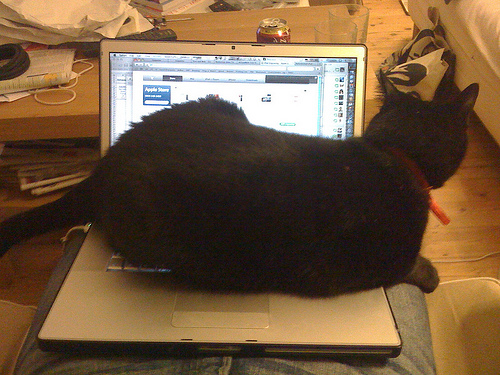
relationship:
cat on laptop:
[0, 67, 479, 294] [34, 36, 404, 361]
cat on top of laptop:
[0, 67, 479, 294] [44, 49, 419, 349]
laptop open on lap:
[34, 36, 404, 361] [27, 226, 439, 370]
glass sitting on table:
[311, 19, 360, 48] [54, 7, 364, 106]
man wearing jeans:
[42, 230, 381, 373] [13, 229, 433, 371]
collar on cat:
[383, 142, 450, 232] [0, 67, 479, 294]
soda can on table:
[258, 17, 290, 47] [4, 9, 386, 275]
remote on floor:
[393, 0, 414, 20] [462, 194, 484, 241]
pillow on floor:
[373, 36, 464, 102] [404, 148, 479, 278]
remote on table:
[85, 24, 178, 57] [6, 6, 366, 136]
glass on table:
[271, 0, 395, 72] [4, 5, 437, 360]